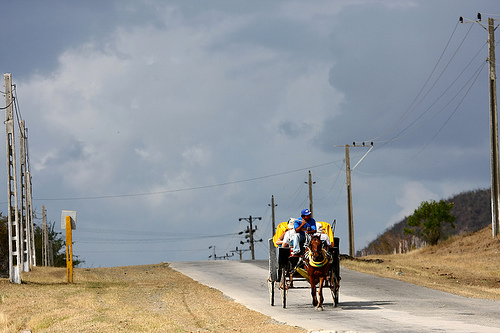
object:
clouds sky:
[0, 0, 500, 247]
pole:
[344, 141, 354, 259]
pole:
[488, 16, 498, 237]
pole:
[308, 167, 313, 218]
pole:
[271, 189, 275, 258]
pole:
[249, 212, 253, 262]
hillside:
[358, 183, 499, 269]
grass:
[0, 263, 311, 333]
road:
[166, 257, 499, 331]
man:
[290, 207, 323, 257]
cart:
[269, 234, 342, 311]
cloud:
[11, 0, 500, 216]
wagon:
[253, 218, 368, 310]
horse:
[289, 228, 339, 311]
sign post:
[66, 216, 73, 279]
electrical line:
[254, 8, 483, 235]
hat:
[301, 208, 313, 215]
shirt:
[294, 216, 316, 233]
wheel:
[281, 267, 288, 308]